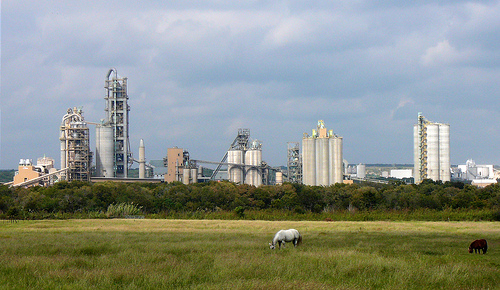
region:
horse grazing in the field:
[260, 221, 307, 254]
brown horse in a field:
[465, 237, 492, 259]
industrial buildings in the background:
[6, 64, 495, 189]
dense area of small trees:
[0, 174, 496, 220]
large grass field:
[0, 222, 498, 289]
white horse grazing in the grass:
[267, 229, 299, 251]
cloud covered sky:
[1, 4, 496, 167]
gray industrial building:
[300, 119, 343, 185]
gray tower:
[95, 64, 130, 178]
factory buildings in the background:
[5, 59, 451, 184]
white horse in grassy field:
[267, 225, 307, 254]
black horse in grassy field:
[464, 234, 493, 259]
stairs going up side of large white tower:
[413, 122, 433, 188]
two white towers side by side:
[407, 108, 454, 188]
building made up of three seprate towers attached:
[294, 116, 347, 194]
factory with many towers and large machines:
[2, 57, 498, 187]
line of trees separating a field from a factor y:
[5, 166, 499, 228]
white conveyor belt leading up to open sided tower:
[2, 105, 94, 193]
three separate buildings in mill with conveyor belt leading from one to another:
[158, 128, 302, 190]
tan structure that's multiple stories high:
[159, 143, 189, 185]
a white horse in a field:
[269, 226, 299, 248]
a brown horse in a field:
[468, 236, 490, 254]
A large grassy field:
[3, 216, 496, 288]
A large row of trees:
[1, 178, 499, 220]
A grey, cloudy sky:
[2, 2, 497, 169]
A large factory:
[4, 66, 499, 185]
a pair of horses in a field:
[268, 227, 488, 254]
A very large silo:
[93, 125, 116, 178]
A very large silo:
[228, 147, 243, 181]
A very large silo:
[245, 146, 264, 186]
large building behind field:
[402, 104, 463, 188]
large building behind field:
[293, 117, 350, 191]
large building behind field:
[222, 125, 272, 185]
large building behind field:
[162, 142, 201, 184]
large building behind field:
[90, 61, 136, 180]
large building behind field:
[52, 104, 97, 183]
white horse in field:
[266, 224, 306, 254]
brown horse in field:
[461, 228, 498, 261]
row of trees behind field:
[0, 173, 497, 223]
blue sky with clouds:
[0, 3, 499, 160]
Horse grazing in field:
[265, 225, 305, 253]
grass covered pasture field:
[3, 220, 499, 288]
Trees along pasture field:
[1, 180, 498, 215]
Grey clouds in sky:
[7, 9, 499, 166]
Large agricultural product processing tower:
[58, 106, 90, 183]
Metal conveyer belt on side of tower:
[206, 127, 248, 182]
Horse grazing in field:
[461, 235, 494, 258]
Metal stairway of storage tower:
[418, 114, 430, 184]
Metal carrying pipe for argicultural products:
[103, 63, 120, 123]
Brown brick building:
[163, 143, 190, 183]